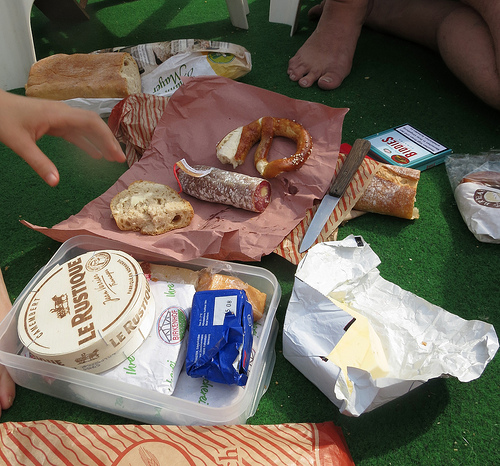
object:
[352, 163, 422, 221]
bread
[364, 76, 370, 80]
crumb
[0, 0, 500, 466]
ground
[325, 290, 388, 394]
butter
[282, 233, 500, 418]
paper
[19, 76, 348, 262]
paper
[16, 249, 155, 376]
container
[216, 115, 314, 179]
bread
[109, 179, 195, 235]
bread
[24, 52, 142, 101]
bread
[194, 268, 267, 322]
bread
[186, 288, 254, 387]
blue food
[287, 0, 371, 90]
foot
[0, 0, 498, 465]
surface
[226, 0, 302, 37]
seats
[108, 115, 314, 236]
food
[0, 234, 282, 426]
container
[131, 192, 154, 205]
butter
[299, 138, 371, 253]
knife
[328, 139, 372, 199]
handle